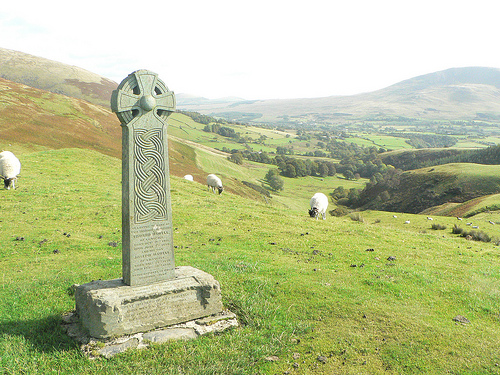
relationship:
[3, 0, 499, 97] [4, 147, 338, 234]
sky above sheep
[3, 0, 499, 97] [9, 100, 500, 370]
sky above grass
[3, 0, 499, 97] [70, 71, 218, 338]
sky above epitaph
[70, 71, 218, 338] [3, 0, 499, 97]
epitaph under sky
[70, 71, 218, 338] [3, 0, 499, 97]
epitaph below sky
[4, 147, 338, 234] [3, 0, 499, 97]
sheep below sky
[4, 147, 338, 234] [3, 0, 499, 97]
sheep under sky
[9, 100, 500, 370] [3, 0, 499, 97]
grass under sky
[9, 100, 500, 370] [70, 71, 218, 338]
grass near epitaph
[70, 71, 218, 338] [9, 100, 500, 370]
epitaph near grass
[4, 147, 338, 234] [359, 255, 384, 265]
sheep eating grass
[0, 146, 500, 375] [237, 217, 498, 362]
grass on ground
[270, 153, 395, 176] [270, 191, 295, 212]
trees below hill